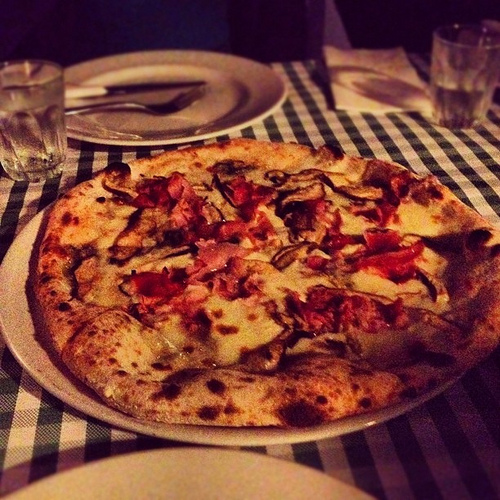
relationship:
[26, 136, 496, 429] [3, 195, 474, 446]
pizza on top of plate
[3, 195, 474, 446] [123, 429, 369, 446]
plate has edge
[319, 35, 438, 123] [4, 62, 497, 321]
napkin on top of table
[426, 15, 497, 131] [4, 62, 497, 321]
glass on top of table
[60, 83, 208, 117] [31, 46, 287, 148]
fork on plate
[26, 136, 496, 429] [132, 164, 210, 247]
pizza has toppings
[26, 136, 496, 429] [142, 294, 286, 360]
pizza has cheese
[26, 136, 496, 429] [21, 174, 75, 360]
pizza has crust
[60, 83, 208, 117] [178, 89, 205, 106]
fork has prongs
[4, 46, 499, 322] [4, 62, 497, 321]
table cloth on table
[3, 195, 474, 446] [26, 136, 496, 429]
plate under pizza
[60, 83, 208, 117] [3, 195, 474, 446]
fork on top of plate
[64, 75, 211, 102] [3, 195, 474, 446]
knife on top of plate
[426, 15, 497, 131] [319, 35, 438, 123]
glass next to napkin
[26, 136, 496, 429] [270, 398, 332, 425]
pizza has burnt spot